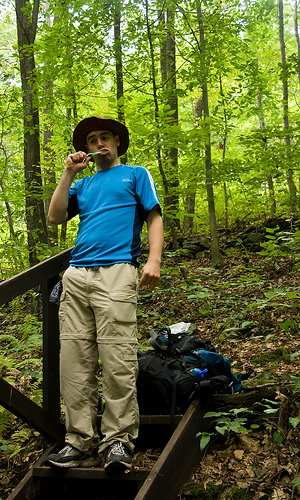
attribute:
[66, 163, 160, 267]
t-shirt — blue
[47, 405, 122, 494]
steps — wooden 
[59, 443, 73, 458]
laces — white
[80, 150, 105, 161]
toothbrush — green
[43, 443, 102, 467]
sneaker — man's, grey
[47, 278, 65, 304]
bandana — blue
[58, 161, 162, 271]
t shirt — blue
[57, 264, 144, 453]
pants — beige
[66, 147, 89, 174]
hand — man's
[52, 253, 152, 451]
pants — cargo, khaki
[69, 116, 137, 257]
man — white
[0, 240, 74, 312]
railling — wooden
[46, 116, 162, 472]
man — young, grey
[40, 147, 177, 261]
shirt — blue , black 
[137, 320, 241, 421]
backpack — black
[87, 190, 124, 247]
shirt — blue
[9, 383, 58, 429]
brace — wooden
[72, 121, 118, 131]
hat — dark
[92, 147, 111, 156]
mouth — man's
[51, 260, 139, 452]
pants — khaki